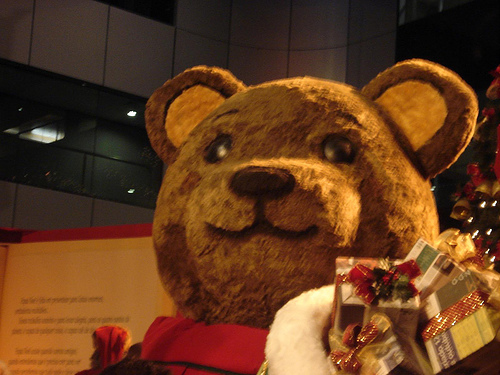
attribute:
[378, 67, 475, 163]
bears ear — brown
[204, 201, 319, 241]
mouth — brown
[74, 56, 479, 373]
stuffed bear — large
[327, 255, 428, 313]
bow — red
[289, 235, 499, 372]
boxes — gift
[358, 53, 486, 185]
ear — brown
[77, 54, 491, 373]
bear — brown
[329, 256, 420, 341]
gift — boxed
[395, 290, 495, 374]
gift — boxed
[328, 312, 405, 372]
gift — boxed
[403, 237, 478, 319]
gift — boxed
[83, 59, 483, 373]
teddy bear — brown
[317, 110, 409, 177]
eye — brown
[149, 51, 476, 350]
bear — brown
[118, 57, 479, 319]
teddy bear — brown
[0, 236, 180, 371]
wall — wooden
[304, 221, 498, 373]
boxes — wrapped, gifts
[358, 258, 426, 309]
bow — red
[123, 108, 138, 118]
lamp — round, white, ceiling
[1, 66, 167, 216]
windows — round, reflective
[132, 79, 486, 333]
teddy bear — huge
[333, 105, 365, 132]
eyebrow — brown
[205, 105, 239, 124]
eyebrow — brown